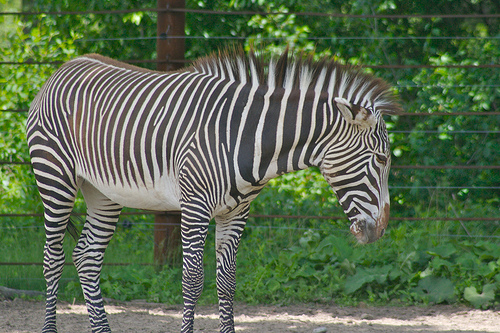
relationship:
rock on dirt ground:
[309, 322, 329, 331] [1, 297, 499, 330]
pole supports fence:
[154, 14, 183, 266] [0, 13, 499, 291]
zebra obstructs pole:
[35, 54, 387, 320] [153, 2, 185, 269]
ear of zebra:
[321, 106, 351, 154] [25, 42, 391, 332]